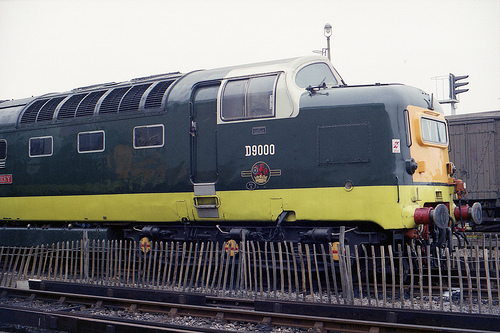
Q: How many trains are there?
A: One.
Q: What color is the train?
A: Navy.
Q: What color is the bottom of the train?
A: Yellow.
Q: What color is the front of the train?
A: Orange.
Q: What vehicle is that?
A: Train.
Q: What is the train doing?
A: Moving.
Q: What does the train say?
A: D9000.